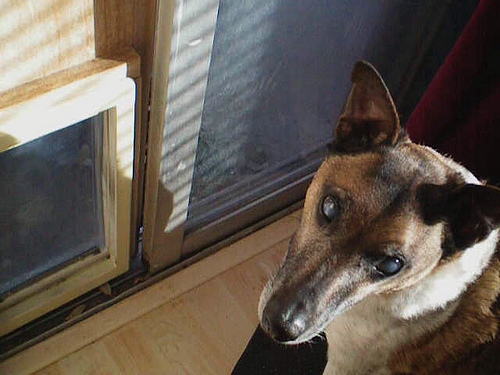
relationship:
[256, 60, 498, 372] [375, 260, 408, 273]
dog has eye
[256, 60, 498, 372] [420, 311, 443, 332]
dog has fur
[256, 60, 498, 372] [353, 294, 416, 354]
dog has fur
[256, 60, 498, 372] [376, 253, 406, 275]
dog has eye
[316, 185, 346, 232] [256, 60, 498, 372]
eye belonging to dog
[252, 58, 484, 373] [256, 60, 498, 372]
fur covering dog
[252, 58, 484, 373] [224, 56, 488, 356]
fur covering dog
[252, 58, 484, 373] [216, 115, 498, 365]
fur covering dog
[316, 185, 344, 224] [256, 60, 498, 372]
eye belonging to dog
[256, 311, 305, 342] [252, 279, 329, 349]
nose belonging to dog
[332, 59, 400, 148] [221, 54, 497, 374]
ear belonging to dog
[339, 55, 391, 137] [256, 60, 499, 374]
ear belonging to dog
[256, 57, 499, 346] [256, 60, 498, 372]
head belonging to dog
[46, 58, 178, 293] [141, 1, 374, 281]
board attached to door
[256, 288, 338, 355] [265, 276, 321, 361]
nose of dog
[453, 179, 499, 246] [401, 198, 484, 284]
ear of dog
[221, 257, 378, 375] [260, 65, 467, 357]
head of dog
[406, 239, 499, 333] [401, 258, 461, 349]
fur of dog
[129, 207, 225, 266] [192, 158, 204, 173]
sheep standing in grass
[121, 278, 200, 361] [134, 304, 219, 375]
sheep standing in grass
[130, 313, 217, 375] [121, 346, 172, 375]
sheep standing in grass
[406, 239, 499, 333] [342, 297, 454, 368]
fur of dog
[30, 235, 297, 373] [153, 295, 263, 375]
floor made of wood